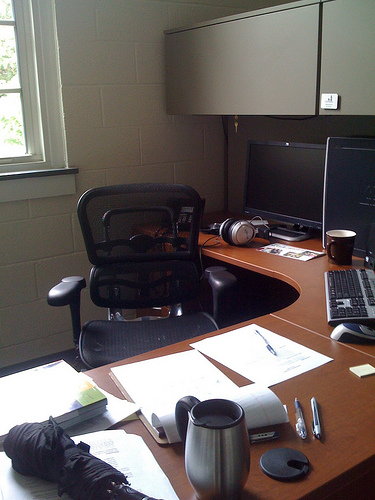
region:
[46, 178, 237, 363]
Black office chair in front of desk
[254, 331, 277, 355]
Pen on top of paper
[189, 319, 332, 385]
Paper on top of desk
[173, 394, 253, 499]
Silver mug on top of desk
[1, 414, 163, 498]
Black umbrella on top of a stack of white papers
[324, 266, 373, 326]
Keyboard is gray and black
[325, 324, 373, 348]
Mouse next to keyboard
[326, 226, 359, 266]
Brown mug by monitor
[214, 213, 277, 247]
Large headphones next to chair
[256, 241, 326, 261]
Brochure by brown mug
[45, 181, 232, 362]
Black colored computer chair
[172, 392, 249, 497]
A metal coffee mug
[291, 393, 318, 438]
Two pens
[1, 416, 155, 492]
A folded black umbrella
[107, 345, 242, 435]
A legal notepad on a clipboard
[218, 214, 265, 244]
A pair of folded headphone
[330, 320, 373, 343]
A computer mouse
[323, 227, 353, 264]
A brown colored coffee mug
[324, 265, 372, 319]
A computer keyboard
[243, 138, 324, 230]
A computer monitor powered off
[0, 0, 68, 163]
White window behind black office chair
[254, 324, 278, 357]
Pen on white paper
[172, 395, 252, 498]
Silver mug on wooden desk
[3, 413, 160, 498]
Black umbrella beside silver mug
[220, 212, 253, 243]
Large headphones in front of monitor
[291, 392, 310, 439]
Pen next to pen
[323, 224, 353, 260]
Brown mug by keyboard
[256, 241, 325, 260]
Brochure by large headphones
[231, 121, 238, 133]
Key dangling by monitor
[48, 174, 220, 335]
black office chair next to a desk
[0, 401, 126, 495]
black umbrella on desk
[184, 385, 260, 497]
coffee mug on desk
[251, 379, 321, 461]
ink pens on a desk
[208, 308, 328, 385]
paper on a desk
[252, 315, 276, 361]
ink pen on a piece of paper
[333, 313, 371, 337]
mouse next to a key board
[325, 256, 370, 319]
keyboard on a desk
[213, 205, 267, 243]
head phones on a desk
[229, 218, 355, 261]
mug on a desk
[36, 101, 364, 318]
a small computer office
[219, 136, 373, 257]
a computer screen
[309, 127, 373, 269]
a computer monitor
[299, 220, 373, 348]
a keyboard and mouse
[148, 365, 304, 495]
a coffee mug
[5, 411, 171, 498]
an umbrella on the table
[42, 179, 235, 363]
a chair by the desk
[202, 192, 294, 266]
headphones near the monitor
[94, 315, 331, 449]
pen and paper on the desk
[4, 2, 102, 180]
a window in the background